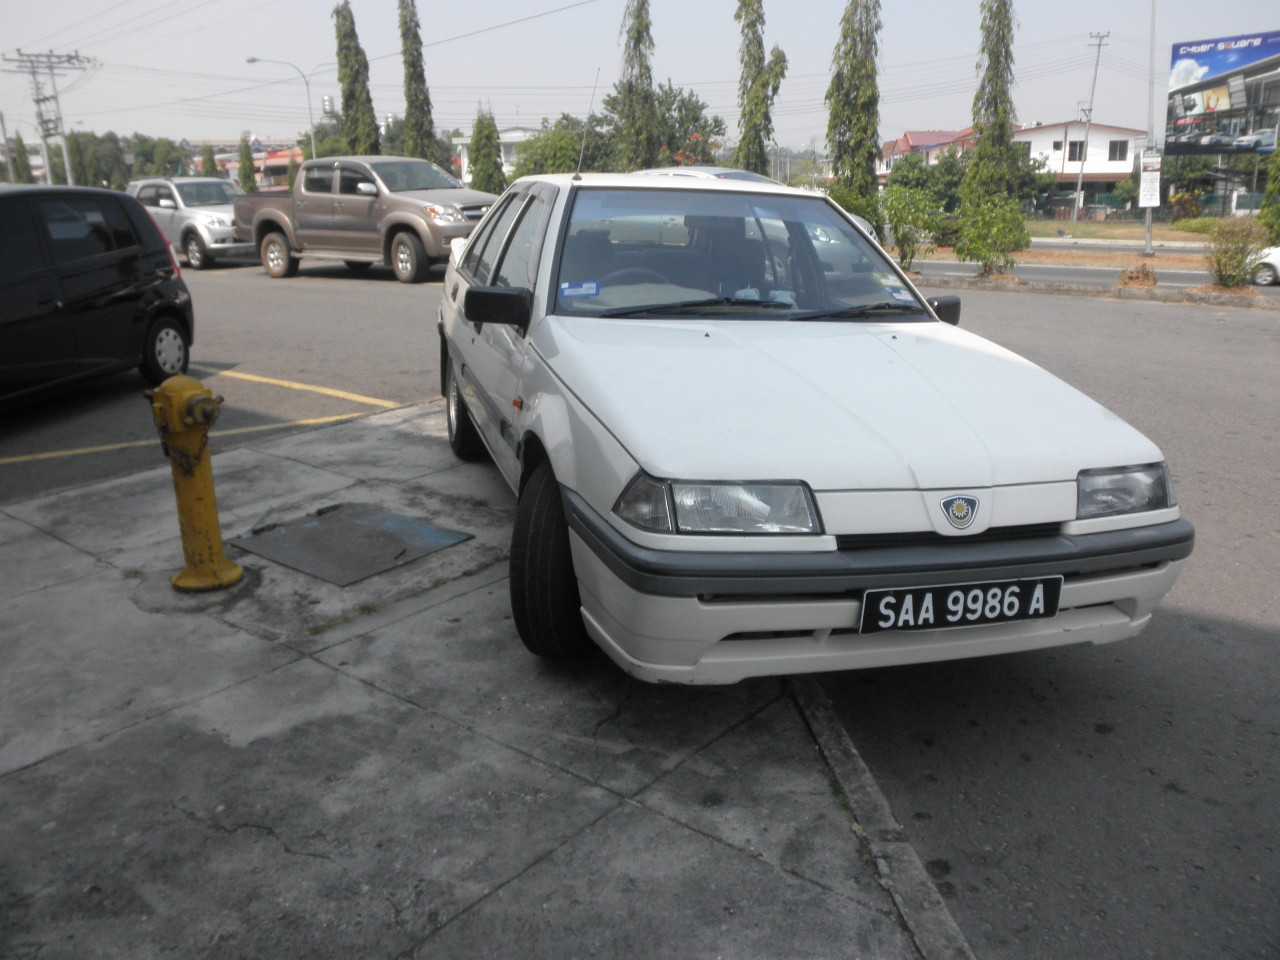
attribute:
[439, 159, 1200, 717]
car — white 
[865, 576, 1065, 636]
plate — black and white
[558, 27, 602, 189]
antenna — short and silver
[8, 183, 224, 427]
car — black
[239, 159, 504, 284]
truck — gray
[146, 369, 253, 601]
hydrant — Yellow 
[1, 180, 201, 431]
car — Black 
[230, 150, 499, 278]
truck — grey 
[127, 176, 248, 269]
car — grey 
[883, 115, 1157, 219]
house — White 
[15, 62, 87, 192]
pole — Silver 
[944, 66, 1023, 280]
tree — Tall , skinny 